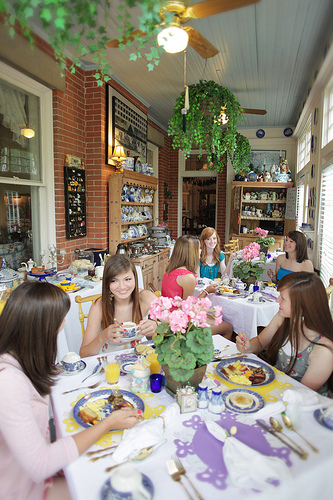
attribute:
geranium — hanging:
[166, 79, 248, 167]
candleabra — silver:
[41, 245, 67, 271]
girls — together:
[0, 226, 331, 499]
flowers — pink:
[147, 294, 223, 332]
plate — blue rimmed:
[73, 389, 146, 429]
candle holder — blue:
[149, 372, 163, 393]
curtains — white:
[2, 83, 32, 148]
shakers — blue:
[194, 382, 225, 413]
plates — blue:
[253, 128, 292, 138]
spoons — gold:
[269, 413, 319, 456]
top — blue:
[196, 250, 225, 279]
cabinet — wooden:
[107, 170, 158, 254]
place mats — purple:
[165, 402, 305, 496]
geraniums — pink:
[147, 284, 221, 346]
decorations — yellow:
[218, 354, 277, 403]